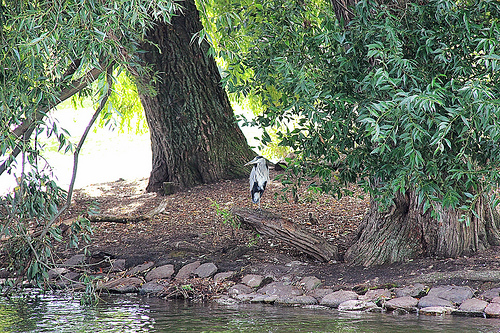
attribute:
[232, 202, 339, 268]
limb — wooden, brown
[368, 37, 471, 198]
tree — large, stump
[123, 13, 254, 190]
trunk — large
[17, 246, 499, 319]
rocks — double layered, large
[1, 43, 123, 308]
overhanging branch — large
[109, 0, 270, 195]
tree — large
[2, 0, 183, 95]
leaves — green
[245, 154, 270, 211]
bird — white, black, large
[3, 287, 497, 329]
water — reflective, rippled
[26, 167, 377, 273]
hill — leaf covered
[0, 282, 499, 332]
pond — edged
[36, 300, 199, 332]
water — calm, green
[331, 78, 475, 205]
leaves — green, large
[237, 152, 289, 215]
bird — white , black , gray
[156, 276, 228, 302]
pile — leaves, twigs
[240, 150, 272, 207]
bird — black, white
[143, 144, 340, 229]
tree trunk — mossy, large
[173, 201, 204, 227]
leaves — brown